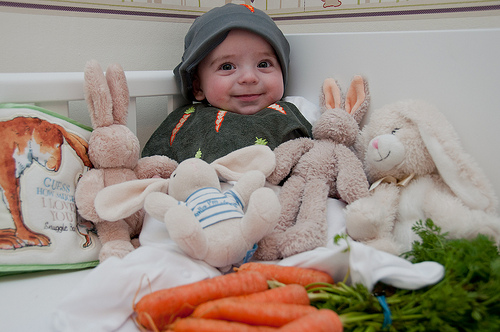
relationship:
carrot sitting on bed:
[126, 262, 272, 329] [53, 10, 493, 297]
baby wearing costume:
[146, 0, 358, 189] [172, 106, 307, 153]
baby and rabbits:
[146, 0, 358, 189] [68, 53, 485, 266]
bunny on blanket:
[5, 115, 65, 243] [1, 101, 114, 272]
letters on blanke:
[31, 173, 77, 204] [10, 150, 167, 292]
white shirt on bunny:
[178, 187, 246, 227] [95, 141, 279, 266]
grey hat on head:
[173, 1, 288, 106] [192, 27, 283, 114]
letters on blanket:
[38, 218, 74, 236] [0, 97, 102, 277]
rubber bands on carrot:
[375, 292, 394, 330] [126, 262, 272, 329]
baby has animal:
[146, 0, 358, 189] [75, 57, 183, 266]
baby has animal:
[146, 0, 358, 189] [95, 145, 282, 266]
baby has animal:
[146, 0, 358, 189] [255, 76, 370, 261]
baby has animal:
[146, 0, 358, 189] [344, 98, 484, 270]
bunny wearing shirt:
[95, 141, 279, 266] [172, 186, 249, 228]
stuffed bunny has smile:
[346, 93, 498, 255] [372, 150, 391, 164]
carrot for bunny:
[236, 262, 331, 286] [95, 141, 279, 266]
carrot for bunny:
[126, 262, 272, 329] [356, 104, 497, 246]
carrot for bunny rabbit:
[126, 262, 272, 329] [255, 73, 373, 262]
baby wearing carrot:
[146, 0, 358, 189] [126, 262, 272, 329]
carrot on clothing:
[126, 262, 272, 329] [140, 101, 312, 152]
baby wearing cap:
[146, 0, 358, 189] [173, 4, 291, 94]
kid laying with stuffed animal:
[141, 3, 311, 168] [75, 55, 177, 262]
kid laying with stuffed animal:
[141, 3, 311, 168] [100, 141, 281, 265]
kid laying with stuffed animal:
[141, 3, 311, 168] [252, 72, 369, 257]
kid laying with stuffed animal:
[141, 3, 311, 168] [341, 93, 488, 237]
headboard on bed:
[1, 68, 183, 135] [0, 26, 499, 330]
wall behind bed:
[21, 15, 156, 62] [0, 43, 229, 198]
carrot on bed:
[126, 262, 272, 329] [2, 23, 497, 240]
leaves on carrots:
[308, 217, 496, 328] [131, 259, 343, 329]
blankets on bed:
[23, 238, 213, 330] [0, 68, 497, 329]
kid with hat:
[141, 3, 311, 168] [177, 1, 296, 57]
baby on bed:
[146, 0, 358, 189] [30, 63, 355, 299]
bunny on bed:
[356, 104, 497, 246] [0, 68, 497, 329]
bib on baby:
[0, 102, 107, 274] [183, 15, 303, 185]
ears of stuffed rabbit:
[315, 71, 382, 112] [280, 97, 366, 234]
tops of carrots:
[332, 244, 500, 327] [151, 256, 359, 324]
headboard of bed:
[1, 68, 183, 135] [0, 68, 497, 329]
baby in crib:
[146, 0, 358, 189] [32, 66, 263, 200]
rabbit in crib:
[360, 103, 489, 258] [15, 70, 334, 205]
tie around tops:
[366, 286, 394, 331] [332, 244, 472, 330]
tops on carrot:
[332, 244, 472, 330] [139, 249, 317, 330]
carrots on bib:
[165, 105, 227, 147] [201, 108, 261, 151]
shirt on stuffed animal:
[175, 183, 246, 223] [147, 149, 289, 261]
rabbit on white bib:
[276, 85, 350, 208] [149, 97, 306, 179]